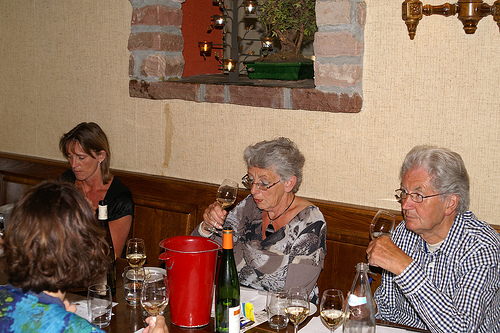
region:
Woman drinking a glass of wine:
[191, 133, 329, 312]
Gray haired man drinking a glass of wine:
[351, 136, 495, 326]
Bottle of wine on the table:
[83, 195, 123, 295]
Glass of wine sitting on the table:
[311, 282, 348, 331]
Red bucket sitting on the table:
[155, 226, 221, 331]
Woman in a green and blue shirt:
[0, 180, 106, 331]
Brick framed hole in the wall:
[113, 4, 369, 116]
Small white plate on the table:
[124, 261, 171, 287]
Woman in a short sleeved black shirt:
[52, 117, 135, 261]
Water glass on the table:
[81, 277, 121, 329]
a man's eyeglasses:
[395, 185, 456, 200]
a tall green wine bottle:
[215, 221, 243, 331]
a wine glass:
[317, 289, 350, 331]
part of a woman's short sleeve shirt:
[88, 182, 136, 227]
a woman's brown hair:
[0, 178, 112, 293]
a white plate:
[122, 260, 170, 284]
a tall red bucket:
[157, 230, 219, 328]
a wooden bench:
[317, 198, 397, 309]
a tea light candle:
[198, 40, 213, 55]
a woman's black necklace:
[260, 195, 298, 237]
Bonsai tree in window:
[244, 0, 323, 106]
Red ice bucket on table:
[146, 222, 226, 331]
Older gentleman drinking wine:
[364, 149, 486, 264]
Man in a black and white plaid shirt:
[389, 155, 499, 328]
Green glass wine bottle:
[213, 228, 243, 330]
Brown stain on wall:
[143, 97, 195, 186]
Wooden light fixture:
[388, 1, 497, 50]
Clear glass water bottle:
[334, 258, 378, 331]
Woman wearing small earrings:
[61, 121, 111, 186]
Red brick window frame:
[130, 1, 365, 112]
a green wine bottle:
[223, 232, 243, 319]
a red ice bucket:
[165, 235, 220, 326]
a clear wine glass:
[145, 270, 176, 325]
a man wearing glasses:
[396, 183, 465, 259]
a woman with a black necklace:
[235, 140, 315, 300]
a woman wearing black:
[60, 125, 145, 255]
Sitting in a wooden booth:
[155, 175, 360, 285]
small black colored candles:
[210, 10, 295, 70]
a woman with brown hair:
[15, 190, 110, 325]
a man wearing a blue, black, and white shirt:
[377, 180, 492, 320]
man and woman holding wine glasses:
[198, 122, 478, 321]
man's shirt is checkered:
[378, 209, 494, 330]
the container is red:
[148, 213, 246, 331]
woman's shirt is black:
[42, 160, 154, 262]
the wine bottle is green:
[208, 243, 256, 328]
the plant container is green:
[230, 53, 320, 85]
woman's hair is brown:
[2, 169, 129, 311]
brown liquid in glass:
[120, 229, 146, 273]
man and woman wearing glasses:
[239, 164, 453, 213]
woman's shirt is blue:
[1, 282, 90, 331]